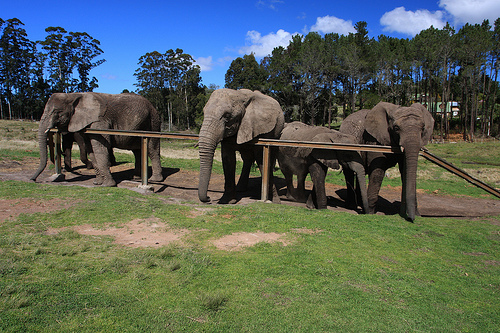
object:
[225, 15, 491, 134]
tree line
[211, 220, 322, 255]
dirt patch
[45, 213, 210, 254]
dirt patch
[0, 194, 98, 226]
dirt patch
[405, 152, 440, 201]
ground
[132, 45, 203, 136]
tree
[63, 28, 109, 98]
tree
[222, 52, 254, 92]
tree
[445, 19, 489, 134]
tree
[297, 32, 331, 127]
tree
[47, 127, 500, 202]
barrier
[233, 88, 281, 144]
ear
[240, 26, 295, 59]
clouds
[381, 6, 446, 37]
clouds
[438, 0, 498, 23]
clouds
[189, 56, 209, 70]
clouds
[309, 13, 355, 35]
clouds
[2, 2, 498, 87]
sky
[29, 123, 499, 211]
rail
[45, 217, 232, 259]
dirt grass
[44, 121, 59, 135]
elephant tusk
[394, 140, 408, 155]
elephant tusk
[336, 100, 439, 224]
animal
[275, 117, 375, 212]
animal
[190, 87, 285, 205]
animal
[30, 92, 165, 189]
animal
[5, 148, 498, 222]
trail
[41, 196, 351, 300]
patches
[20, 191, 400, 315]
grass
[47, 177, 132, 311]
floor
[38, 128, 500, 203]
fence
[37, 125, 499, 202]
rail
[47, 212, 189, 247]
dirt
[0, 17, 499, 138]
row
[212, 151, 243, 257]
standing